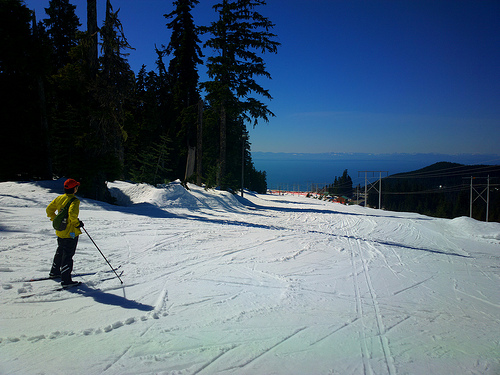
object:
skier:
[46, 178, 85, 288]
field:
[1, 180, 500, 375]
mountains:
[246, 149, 500, 225]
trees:
[194, 0, 283, 192]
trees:
[151, 0, 204, 186]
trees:
[92, 1, 139, 184]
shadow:
[80, 186, 475, 260]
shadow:
[229, 189, 437, 221]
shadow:
[61, 281, 156, 311]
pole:
[81, 227, 126, 285]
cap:
[64, 179, 80, 190]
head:
[64, 179, 81, 195]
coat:
[45, 193, 82, 239]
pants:
[49, 236, 79, 283]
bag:
[53, 197, 77, 232]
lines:
[330, 160, 499, 197]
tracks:
[341, 226, 399, 374]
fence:
[266, 191, 311, 197]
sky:
[17, 0, 500, 157]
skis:
[6, 261, 125, 300]